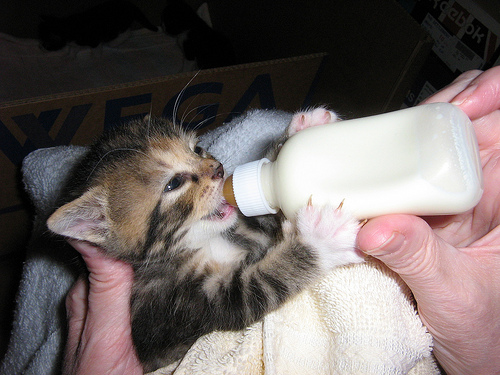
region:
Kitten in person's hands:
[41, 112, 366, 362]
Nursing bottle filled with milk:
[222, 101, 481, 225]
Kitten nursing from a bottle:
[50, 71, 483, 368]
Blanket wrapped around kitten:
[16, 106, 433, 373]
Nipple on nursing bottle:
[221, 171, 235, 215]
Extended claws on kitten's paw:
[274, 193, 369, 223]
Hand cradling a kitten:
[53, 236, 149, 371]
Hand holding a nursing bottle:
[350, 71, 495, 373]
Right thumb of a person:
[357, 216, 495, 330]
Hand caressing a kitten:
[56, 235, 146, 372]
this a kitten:
[28, 45, 451, 364]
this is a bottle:
[188, 93, 455, 258]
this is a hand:
[314, 73, 491, 363]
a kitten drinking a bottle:
[55, 76, 499, 356]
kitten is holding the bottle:
[206, 85, 431, 267]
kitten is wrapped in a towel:
[30, 91, 446, 357]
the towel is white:
[25, 102, 460, 370]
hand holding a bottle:
[336, 42, 496, 374]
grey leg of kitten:
[37, 236, 302, 373]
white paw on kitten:
[251, 170, 388, 285]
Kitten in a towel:
[43, 104, 350, 369]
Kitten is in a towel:
[42, 102, 344, 374]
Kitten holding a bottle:
[207, 89, 487, 233]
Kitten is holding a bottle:
[218, 97, 488, 224]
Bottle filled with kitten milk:
[211, 97, 484, 230]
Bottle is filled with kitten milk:
[211, 100, 486, 228]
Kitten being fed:
[44, 110, 356, 367]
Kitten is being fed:
[37, 104, 377, 371]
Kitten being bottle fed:
[58, 103, 373, 373]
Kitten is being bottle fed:
[30, 98, 382, 373]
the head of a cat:
[87, 90, 244, 308]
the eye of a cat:
[147, 150, 213, 215]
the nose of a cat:
[198, 155, 248, 190]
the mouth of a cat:
[186, 157, 252, 237]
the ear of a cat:
[37, 173, 135, 253]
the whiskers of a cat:
[148, 110, 280, 225]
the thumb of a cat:
[343, 189, 463, 299]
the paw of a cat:
[256, 178, 383, 298]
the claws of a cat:
[294, 171, 386, 292]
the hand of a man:
[367, 143, 491, 311]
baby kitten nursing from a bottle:
[40, 95, 370, 373]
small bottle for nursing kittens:
[212, 96, 489, 240]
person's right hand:
[355, 59, 497, 373]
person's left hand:
[42, 228, 157, 373]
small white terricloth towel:
[2, 102, 449, 372]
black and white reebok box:
[407, 1, 498, 86]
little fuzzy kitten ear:
[44, 178, 122, 259]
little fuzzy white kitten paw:
[292, 186, 369, 281]